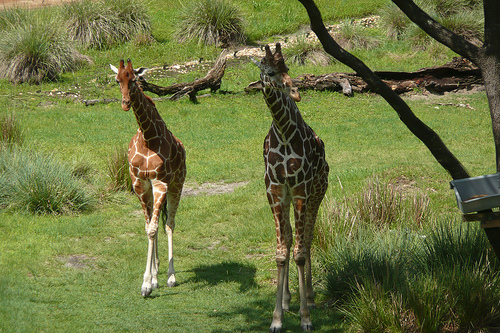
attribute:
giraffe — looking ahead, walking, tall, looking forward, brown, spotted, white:
[108, 60, 188, 290]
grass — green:
[2, 204, 276, 331]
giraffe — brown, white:
[243, 42, 330, 329]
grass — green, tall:
[319, 185, 499, 333]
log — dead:
[133, 51, 230, 102]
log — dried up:
[288, 56, 482, 98]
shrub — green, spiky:
[3, 5, 85, 80]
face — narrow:
[262, 60, 302, 102]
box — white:
[450, 169, 500, 210]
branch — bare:
[394, 1, 479, 61]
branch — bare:
[297, 1, 470, 180]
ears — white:
[109, 65, 150, 78]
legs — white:
[140, 226, 178, 296]